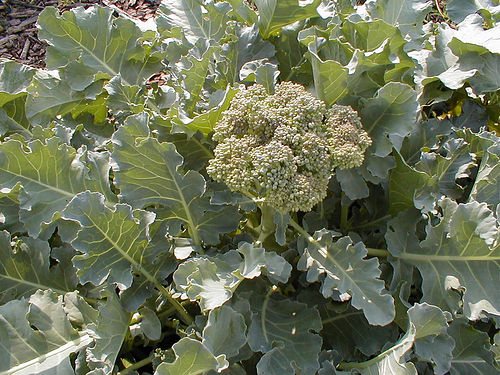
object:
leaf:
[108, 107, 237, 247]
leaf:
[30, 5, 147, 95]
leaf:
[31, 2, 169, 111]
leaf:
[0, 138, 132, 243]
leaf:
[294, 227, 401, 328]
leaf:
[336, 79, 421, 205]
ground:
[243, 65, 285, 157]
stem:
[293, 219, 380, 321]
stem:
[153, 152, 206, 249]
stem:
[40, 12, 168, 109]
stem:
[307, 27, 328, 98]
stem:
[339, 202, 350, 237]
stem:
[422, 23, 496, 83]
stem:
[0, 161, 155, 226]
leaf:
[173, 253, 278, 322]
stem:
[363, 242, 499, 260]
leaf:
[236, 283, 333, 373]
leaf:
[340, 307, 457, 374]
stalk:
[260, 201, 276, 233]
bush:
[0, 1, 496, 370]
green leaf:
[382, 203, 498, 316]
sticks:
[130, 4, 147, 14]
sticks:
[7, 6, 36, 20]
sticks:
[32, 44, 44, 58]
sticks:
[16, 36, 32, 58]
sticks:
[17, 17, 37, 29]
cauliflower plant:
[3, 0, 496, 374]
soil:
[1, 0, 161, 70]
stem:
[157, 284, 194, 327]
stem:
[289, 215, 318, 238]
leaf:
[59, 192, 174, 302]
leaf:
[237, 237, 294, 292]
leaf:
[243, 285, 323, 372]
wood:
[18, 37, 30, 61]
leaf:
[58, 195, 157, 292]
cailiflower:
[205, 80, 374, 220]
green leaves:
[456, 116, 496, 235]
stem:
[158, 296, 197, 326]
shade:
[286, 281, 324, 314]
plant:
[205, 78, 372, 215]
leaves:
[405, 3, 499, 90]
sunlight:
[111, 5, 484, 282]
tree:
[75, 42, 216, 293]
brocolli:
[205, 81, 373, 213]